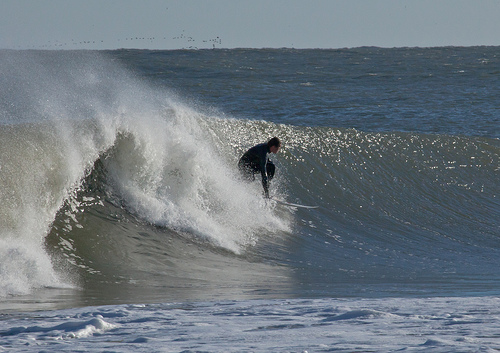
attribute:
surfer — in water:
[234, 135, 289, 203]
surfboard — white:
[269, 191, 321, 216]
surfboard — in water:
[271, 193, 321, 212]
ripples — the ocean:
[322, 133, 367, 160]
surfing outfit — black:
[242, 143, 272, 187]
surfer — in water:
[231, 127, 296, 192]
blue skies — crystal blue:
[183, 3, 348, 49]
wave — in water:
[0, 137, 495, 328]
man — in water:
[237, 132, 284, 203]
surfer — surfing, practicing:
[232, 125, 296, 222]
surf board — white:
[244, 178, 356, 211]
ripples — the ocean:
[132, 211, 293, 302]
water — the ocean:
[335, 142, 499, 239]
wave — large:
[0, 108, 497, 300]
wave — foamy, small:
[3, 315, 123, 345]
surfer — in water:
[224, 121, 381, 236]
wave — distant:
[187, 67, 477, 86]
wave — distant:
[225, 47, 455, 63]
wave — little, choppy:
[275, 76, 325, 92]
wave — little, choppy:
[353, 64, 402, 83]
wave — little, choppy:
[420, 62, 470, 77]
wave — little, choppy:
[431, 60, 478, 82]